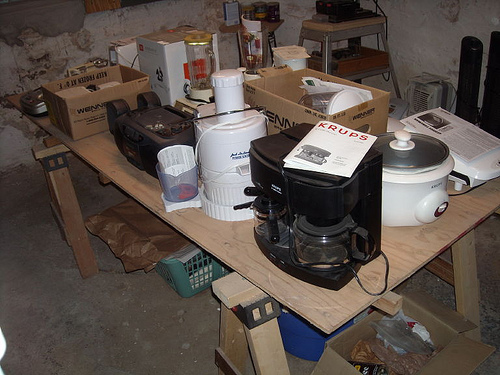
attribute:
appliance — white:
[375, 126, 456, 231]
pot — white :
[356, 124, 442, 236]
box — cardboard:
[242, 56, 399, 172]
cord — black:
[339, 218, 409, 345]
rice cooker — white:
[373, 130, 453, 225]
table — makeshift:
[9, 49, 496, 336]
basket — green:
[162, 233, 218, 292]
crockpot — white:
[372, 127, 459, 229]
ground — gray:
[60, 300, 108, 346]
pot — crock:
[369, 126, 454, 228]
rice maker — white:
[373, 128, 453, 228]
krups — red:
[315, 113, 369, 145]